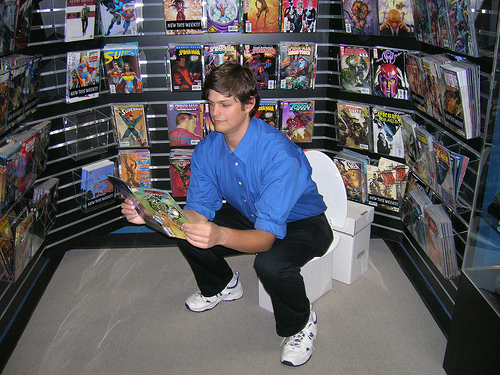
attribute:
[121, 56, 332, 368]
man — sitting, smiling, defecating, defacating, reading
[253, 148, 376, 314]
toilet — fake, small, white, unconnected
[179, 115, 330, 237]
shirt — blue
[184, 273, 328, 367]
sneakers — white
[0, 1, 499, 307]
racks — plexiglass, deep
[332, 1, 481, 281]
comics — hanging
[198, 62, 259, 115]
hair — brown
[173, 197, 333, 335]
pants — black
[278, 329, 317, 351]
laces — white